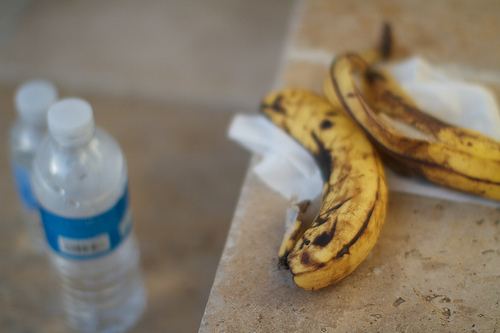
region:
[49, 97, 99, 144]
White plastic cap on water bottle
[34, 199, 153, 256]
blue and white label on water bottle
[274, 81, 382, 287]
browning banana on counter top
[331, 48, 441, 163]
half peeled banana on counter top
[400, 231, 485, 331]
light brown granite counter top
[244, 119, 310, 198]
white plastic bag under banana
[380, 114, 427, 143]
banana still in the peel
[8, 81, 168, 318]
Two plastic water bottles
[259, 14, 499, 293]
two browning bananas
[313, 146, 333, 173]
black bruise on banana peel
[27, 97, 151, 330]
water bottle next to water bottle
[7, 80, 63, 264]
water bottle behind water bottle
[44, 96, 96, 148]
white plastic lid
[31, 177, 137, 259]
blue label on plastic water bottle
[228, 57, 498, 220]
white napkin under 2 bananas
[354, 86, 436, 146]
split on banana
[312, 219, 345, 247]
black mark on banana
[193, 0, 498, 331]
stone ledge under banana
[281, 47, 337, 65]
white mortar line above banana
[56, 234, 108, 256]
upc code on label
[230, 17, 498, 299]
two bananas so overripe they'd taste like grainy sweetened mud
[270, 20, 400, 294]
stems of bananas face away from one another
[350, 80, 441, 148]
a nature-created-not animal-split in one side of a banana thats all but just one big bruise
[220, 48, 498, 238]
perhaps a clearish white plastic bag beneath bananas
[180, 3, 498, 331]
bananas are either on a ledge made from blocks or bench or table made from them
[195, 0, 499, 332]
blocks are mottled, worn at the edge, purposefully pitted during production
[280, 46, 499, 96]
space between blocks is filled with either grout or plaster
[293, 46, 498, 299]
two long dark brown lines delineate edges of both bananas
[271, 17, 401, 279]
both stems are broken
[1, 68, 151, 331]
two individual water bottles- i'm beat, someone else can look up the label!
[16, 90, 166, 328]
water bottle with blue label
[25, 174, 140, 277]
blue label on water bottle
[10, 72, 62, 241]
background water bottle with label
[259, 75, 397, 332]
ripening banana on table top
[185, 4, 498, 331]
brown stone table top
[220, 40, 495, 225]
white paper under bananas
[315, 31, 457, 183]
partially peeled open banana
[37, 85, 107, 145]
plastic cap on water bottle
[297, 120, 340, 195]
black bruise on left banana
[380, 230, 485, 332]
brown spots in stone table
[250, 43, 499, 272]
two bananas on the counter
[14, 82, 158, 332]
two water bottles on the floor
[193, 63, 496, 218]
a white napkin under the bananas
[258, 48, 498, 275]
two very ripe bananas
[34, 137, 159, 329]
a water bottle with a blue label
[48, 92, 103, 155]
white cap on top of bottle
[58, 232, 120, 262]
bar code on water bottle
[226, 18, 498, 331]
bananas on brown countertop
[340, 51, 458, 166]
Peel of one banana is split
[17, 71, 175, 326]
two water bottles with blue labels